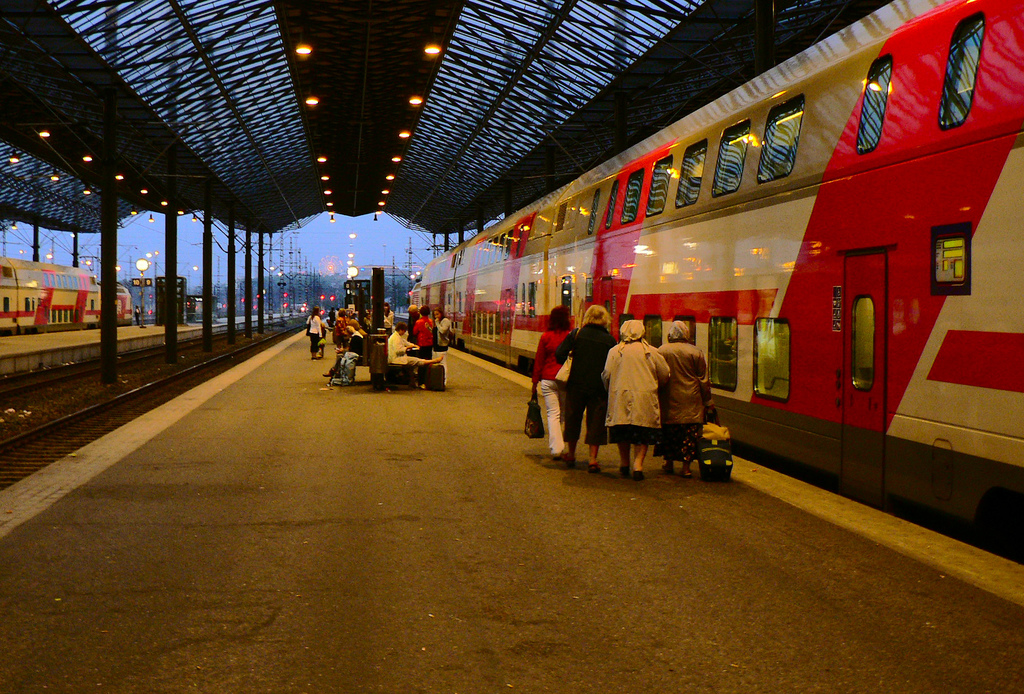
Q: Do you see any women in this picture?
A: Yes, there is a woman.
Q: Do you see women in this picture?
A: Yes, there is a woman.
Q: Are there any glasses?
A: No, there are no glasses.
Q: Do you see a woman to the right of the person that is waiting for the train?
A: Yes, there is a woman to the right of the person.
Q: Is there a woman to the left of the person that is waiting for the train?
A: No, the woman is to the right of the person.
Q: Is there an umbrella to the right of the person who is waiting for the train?
A: No, there is a woman to the right of the person.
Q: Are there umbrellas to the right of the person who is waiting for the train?
A: No, there is a woman to the right of the person.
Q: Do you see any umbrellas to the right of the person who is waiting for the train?
A: No, there is a woman to the right of the person.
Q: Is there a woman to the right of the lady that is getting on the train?
A: No, the woman is to the left of the lady.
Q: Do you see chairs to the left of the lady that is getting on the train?
A: No, there is a woman to the left of the lady.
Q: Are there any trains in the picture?
A: Yes, there is a train.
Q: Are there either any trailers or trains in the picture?
A: Yes, there is a train.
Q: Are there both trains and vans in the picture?
A: No, there is a train but no vans.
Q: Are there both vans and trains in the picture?
A: No, there is a train but no vans.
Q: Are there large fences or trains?
A: Yes, there is a large train.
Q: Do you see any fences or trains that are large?
A: Yes, the train is large.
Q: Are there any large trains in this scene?
A: Yes, there is a large train.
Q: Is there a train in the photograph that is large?
A: Yes, there is a train that is large.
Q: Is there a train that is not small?
A: Yes, there is a large train.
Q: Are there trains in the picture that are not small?
A: Yes, there is a large train.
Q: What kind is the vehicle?
A: The vehicle is a train.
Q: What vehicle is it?
A: The vehicle is a train.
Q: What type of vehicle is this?
A: That is a train.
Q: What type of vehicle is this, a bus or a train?
A: That is a train.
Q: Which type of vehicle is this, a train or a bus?
A: That is a train.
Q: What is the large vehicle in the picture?
A: The vehicle is a train.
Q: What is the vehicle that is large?
A: The vehicle is a train.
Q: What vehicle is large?
A: The vehicle is a train.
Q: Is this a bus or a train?
A: This is a train.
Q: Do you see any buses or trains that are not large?
A: No, there is a train but it is large.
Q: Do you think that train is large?
A: Yes, the train is large.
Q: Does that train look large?
A: Yes, the train is large.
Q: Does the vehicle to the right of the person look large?
A: Yes, the train is large.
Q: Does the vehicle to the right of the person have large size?
A: Yes, the train is large.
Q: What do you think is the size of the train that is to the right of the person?
A: The train is large.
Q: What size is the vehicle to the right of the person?
A: The train is large.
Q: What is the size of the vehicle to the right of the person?
A: The train is large.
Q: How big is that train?
A: The train is large.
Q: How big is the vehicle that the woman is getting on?
A: The train is large.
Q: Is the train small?
A: No, the train is large.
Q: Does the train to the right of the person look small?
A: No, the train is large.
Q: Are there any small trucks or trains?
A: No, there is a train but it is large.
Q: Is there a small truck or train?
A: No, there is a train but it is large.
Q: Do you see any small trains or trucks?
A: No, there is a train but it is large.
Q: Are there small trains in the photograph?
A: No, there is a train but it is large.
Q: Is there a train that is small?
A: No, there is a train but it is large.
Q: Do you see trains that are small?
A: No, there is a train but it is large.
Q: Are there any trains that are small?
A: No, there is a train but it is large.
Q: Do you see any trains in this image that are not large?
A: No, there is a train but it is large.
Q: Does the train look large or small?
A: The train is large.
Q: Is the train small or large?
A: The train is large.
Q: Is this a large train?
A: Yes, this is a large train.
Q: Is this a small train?
A: No, this is a large train.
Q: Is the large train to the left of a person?
A: No, the train is to the right of a person.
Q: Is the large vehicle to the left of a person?
A: No, the train is to the right of a person.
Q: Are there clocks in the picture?
A: No, there are no clocks.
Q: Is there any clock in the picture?
A: No, there are no clocks.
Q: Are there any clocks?
A: No, there are no clocks.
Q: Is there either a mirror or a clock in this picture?
A: No, there are no clocks or mirrors.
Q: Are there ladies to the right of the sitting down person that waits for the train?
A: Yes, there is a lady to the right of the person.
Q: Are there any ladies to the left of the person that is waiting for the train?
A: No, the lady is to the right of the person.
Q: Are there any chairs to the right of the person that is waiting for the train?
A: No, there is a lady to the right of the person.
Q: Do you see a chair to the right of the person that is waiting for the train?
A: No, there is a lady to the right of the person.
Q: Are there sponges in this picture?
A: No, there are no sponges.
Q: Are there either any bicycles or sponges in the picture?
A: No, there are no sponges or bicycles.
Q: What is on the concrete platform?
A: The luggage is on the platform.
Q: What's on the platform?
A: The luggage is on the platform.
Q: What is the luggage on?
A: The luggage is on the platform.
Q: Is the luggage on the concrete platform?
A: Yes, the luggage is on the platform.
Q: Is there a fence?
A: No, there are no fences.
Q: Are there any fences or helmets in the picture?
A: No, there are no fences or helmets.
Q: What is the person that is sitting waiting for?
A: The person is waiting for the train.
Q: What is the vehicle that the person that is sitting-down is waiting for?
A: The vehicle is a train.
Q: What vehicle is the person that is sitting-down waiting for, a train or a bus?
A: The person is waiting for a train.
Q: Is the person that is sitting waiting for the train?
A: Yes, the person is waiting for the train.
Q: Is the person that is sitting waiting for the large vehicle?
A: Yes, the person is waiting for the train.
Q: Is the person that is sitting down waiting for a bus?
A: No, the person is waiting for the train.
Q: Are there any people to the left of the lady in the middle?
A: Yes, there is a person to the left of the lady.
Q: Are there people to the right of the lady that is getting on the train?
A: No, the person is to the left of the lady.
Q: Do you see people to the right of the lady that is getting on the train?
A: No, the person is to the left of the lady.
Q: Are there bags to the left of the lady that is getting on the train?
A: No, there is a person to the left of the lady.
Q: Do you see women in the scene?
A: Yes, there is a woman.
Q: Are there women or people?
A: Yes, there is a woman.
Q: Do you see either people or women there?
A: Yes, there is a woman.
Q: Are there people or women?
A: Yes, there is a woman.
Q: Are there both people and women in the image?
A: Yes, there are both a woman and people.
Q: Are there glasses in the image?
A: No, there are no glasses.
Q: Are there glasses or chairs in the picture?
A: No, there are no glasses or chairs.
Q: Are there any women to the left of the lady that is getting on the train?
A: Yes, there is a woman to the left of the lady.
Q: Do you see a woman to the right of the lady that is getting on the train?
A: No, the woman is to the left of the lady.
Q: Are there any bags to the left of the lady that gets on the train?
A: No, there is a woman to the left of the lady.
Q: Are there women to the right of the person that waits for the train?
A: Yes, there is a woman to the right of the person.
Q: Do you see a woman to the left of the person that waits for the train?
A: No, the woman is to the right of the person.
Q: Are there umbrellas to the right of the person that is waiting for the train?
A: No, there is a woman to the right of the person.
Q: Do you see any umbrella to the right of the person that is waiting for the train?
A: No, there is a woman to the right of the person.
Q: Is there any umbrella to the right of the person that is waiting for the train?
A: No, there is a woman to the right of the person.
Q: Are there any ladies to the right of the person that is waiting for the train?
A: Yes, there is a lady to the right of the person.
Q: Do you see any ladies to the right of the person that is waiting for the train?
A: Yes, there is a lady to the right of the person.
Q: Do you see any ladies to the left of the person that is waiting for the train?
A: No, the lady is to the right of the person.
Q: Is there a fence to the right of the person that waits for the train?
A: No, there is a lady to the right of the person.